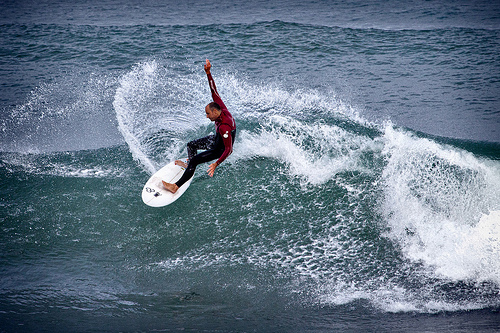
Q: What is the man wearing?
A: Wet suit.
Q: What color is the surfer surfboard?
A: White.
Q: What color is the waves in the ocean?
A: White.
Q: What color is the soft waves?
A: Blue sea.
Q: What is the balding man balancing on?
A: Surfboard.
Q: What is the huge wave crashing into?
A: Surfer.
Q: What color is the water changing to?
A: Deep blue to dark teal.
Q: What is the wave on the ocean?
A: Slightly choppy.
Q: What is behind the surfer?
A: Clear blue water.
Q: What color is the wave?
A: White.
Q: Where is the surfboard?
A: Under the man's feet.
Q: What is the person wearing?
A: Wetsuit.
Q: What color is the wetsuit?
A: Black and red.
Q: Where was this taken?
A: Ocean.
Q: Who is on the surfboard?
A: Surfer.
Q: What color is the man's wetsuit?
A: Red and black.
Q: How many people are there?
A: 1.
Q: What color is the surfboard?
A: White.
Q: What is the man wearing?
A: Wetsuit.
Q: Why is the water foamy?
A: Cresting waves.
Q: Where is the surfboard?
A: Under the man's feet.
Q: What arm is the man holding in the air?
A: Right.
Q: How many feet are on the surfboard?
A: 2.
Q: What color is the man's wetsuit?
A: Red and black.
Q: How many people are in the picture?
A: One.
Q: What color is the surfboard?
A: White.